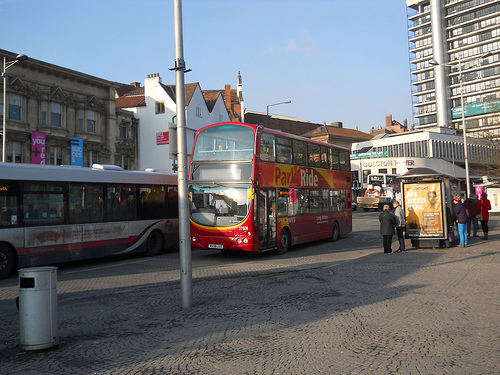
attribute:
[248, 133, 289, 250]
bus — red, tall, two-stories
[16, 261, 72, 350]
trashcan — silver, round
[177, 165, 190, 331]
pole — metal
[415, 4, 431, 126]
building — tall, white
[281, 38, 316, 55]
cloud — white, small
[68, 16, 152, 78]
sky — blue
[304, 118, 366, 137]
roof — red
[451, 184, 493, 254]
people — standing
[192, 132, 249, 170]
window — tall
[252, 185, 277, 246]
door — glass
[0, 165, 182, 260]
bus — white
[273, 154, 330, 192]
billboard — yellow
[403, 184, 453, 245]
sign — yellow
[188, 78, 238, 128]
roof — pitched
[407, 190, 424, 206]
writing — white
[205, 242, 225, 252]
license plate — white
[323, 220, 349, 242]
tire — black